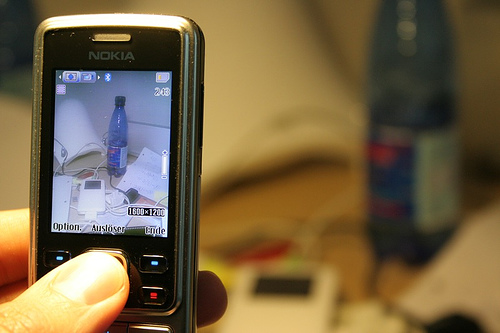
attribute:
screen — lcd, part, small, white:
[52, 79, 172, 216]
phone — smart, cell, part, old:
[4, 6, 214, 287]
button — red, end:
[136, 248, 170, 276]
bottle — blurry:
[322, 15, 472, 284]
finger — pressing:
[48, 252, 128, 307]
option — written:
[51, 218, 162, 243]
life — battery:
[139, 63, 181, 106]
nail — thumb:
[67, 254, 110, 289]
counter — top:
[275, 182, 335, 207]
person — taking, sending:
[11, 199, 130, 325]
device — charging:
[51, 46, 180, 94]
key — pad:
[44, 248, 81, 265]